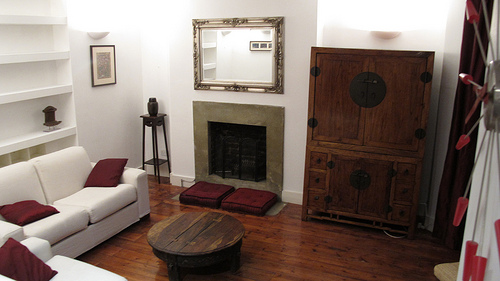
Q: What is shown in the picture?
A: A living room.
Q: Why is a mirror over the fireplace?
A: For decoration.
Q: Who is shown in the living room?
A: No people.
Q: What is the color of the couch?
A: White.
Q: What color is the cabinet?
A: Brown.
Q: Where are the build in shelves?
A: Behind the couch.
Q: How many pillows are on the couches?
A: Three.